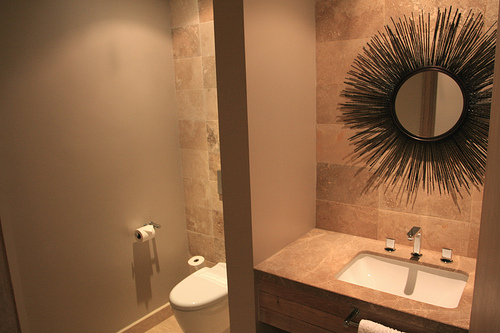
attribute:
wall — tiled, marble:
[305, 0, 497, 260]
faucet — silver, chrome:
[408, 225, 424, 259]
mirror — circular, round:
[395, 69, 465, 140]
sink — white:
[335, 250, 468, 309]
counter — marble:
[252, 227, 478, 330]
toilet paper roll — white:
[188, 256, 206, 272]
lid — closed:
[169, 266, 230, 309]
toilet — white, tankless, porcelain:
[167, 261, 232, 332]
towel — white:
[359, 319, 409, 332]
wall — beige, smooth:
[0, 0, 192, 332]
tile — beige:
[167, 0, 230, 259]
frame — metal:
[339, 8, 496, 213]